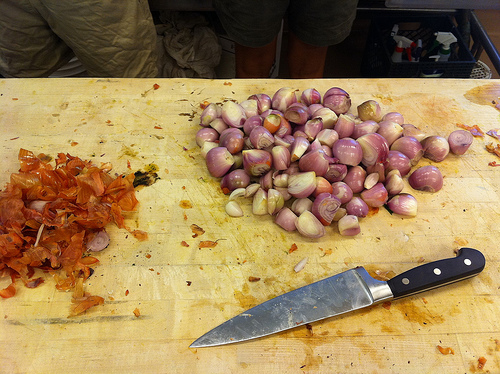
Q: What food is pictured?
A: Red onions.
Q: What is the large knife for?
A: Chopping.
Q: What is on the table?
A: A sharp knife.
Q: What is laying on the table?
A: The skins from onions.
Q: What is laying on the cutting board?
A: Small onions.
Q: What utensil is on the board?
A: Knife.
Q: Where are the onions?
A: On table.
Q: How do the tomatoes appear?
A: Chopped.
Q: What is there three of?
A: Nails on knife.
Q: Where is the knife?
A: On the counter.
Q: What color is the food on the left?
A: Red.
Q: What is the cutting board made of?
A: Wood.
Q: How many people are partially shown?
A: Two.